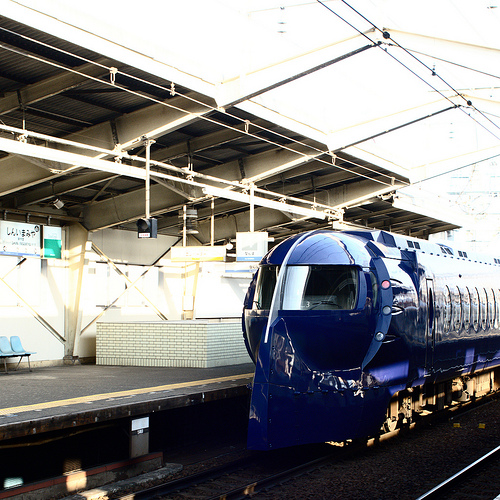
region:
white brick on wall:
[101, 333, 111, 338]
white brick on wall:
[99, 343, 110, 349]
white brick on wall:
[99, 354, 108, 358]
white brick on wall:
[120, 320, 130, 327]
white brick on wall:
[119, 331, 129, 334]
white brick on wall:
[118, 343, 129, 348]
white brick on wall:
[125, 350, 137, 355]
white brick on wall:
[162, 322, 174, 327]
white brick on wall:
[166, 335, 176, 339]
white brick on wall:
[166, 350, 178, 357]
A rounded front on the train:
[245, 249, 367, 437]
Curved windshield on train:
[238, 261, 370, 318]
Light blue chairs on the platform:
[1, 332, 38, 364]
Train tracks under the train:
[216, 436, 457, 499]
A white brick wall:
[90, 306, 235, 373]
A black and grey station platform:
[5, 363, 185, 399]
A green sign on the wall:
[6, 220, 83, 263]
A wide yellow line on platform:
[66, 380, 147, 402]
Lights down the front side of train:
[374, 271, 397, 351]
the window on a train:
[229, 257, 376, 319]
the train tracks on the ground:
[83, 453, 295, 498]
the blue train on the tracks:
[235, 223, 499, 458]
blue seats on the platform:
[0, 328, 43, 370]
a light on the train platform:
[47, 192, 68, 212]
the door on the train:
[418, 273, 445, 375]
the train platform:
[0, 320, 238, 454]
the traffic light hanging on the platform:
[133, 216, 161, 241]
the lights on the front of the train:
[372, 273, 397, 351]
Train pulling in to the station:
[253, 202, 423, 484]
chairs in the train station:
[1, 334, 33, 363]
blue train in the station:
[233, 204, 499, 457]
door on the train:
[417, 272, 445, 384]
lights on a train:
[383, 269, 390, 314]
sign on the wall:
[3, 219, 44, 259]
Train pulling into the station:
[201, 218, 475, 485]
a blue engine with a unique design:
[238, 227, 498, 450]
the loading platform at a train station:
[0, 360, 255, 439]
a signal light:
[137, 217, 157, 238]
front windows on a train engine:
[251, 264, 356, 309]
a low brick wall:
[96, 320, 253, 367]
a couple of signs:
[0, 220, 61, 256]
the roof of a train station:
[0, 0, 499, 260]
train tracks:
[117, 445, 338, 497]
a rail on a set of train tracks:
[415, 443, 499, 498]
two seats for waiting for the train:
[0, 336, 34, 371]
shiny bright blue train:
[238, 224, 498, 426]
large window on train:
[282, 263, 360, 311]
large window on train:
[245, 267, 277, 309]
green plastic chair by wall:
[0, 337, 17, 363]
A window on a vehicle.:
[250, 266, 282, 311]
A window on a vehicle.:
[281, 264, 360, 312]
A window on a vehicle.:
[426, 287, 435, 329]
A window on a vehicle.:
[440, 286, 452, 336]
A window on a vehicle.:
[452, 285, 462, 332]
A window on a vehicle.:
[480, 287, 488, 329]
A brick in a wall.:
[169, 334, 179, 339]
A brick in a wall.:
[124, 357, 128, 365]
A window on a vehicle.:
[406, 240, 416, 248]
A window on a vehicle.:
[414, 241, 421, 249]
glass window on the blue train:
[245, 260, 280, 318]